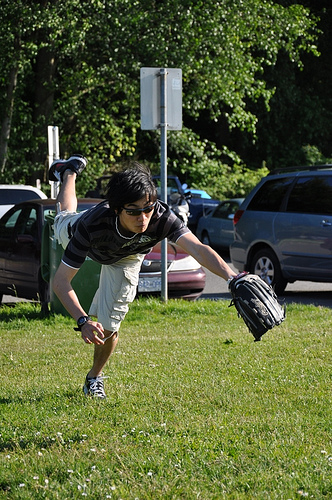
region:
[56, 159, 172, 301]
This man is playing baseball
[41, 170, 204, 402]
Man just caught a ball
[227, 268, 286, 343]
This is a catcher's mitt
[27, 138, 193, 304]
Man is leaning over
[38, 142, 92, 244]
Man's leg is in the air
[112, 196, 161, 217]
Man is wearing sunglasses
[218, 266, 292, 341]
The mitt is black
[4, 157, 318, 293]
A parking lot in the background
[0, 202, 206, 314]
This car is maroon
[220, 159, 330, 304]
This minivan is silver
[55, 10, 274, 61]
The leaves are the color green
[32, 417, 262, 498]
The grass is short and green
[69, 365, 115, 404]
The shoe of the man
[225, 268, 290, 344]
The man is wearing a baseball mitt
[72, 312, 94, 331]
The man has on a watch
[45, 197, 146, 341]
The man is wearing shorts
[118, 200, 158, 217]
The man is wearing sun glasses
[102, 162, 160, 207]
The man has black hair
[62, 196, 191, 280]
The man is wearing a black and grey shirt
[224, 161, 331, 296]
The van is parked in the parking lot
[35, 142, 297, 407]
person bends forward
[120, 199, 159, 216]
sunglasses color black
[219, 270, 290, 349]
the glove of baseball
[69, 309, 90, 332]
a clock on wrist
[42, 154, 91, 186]
blue shoes with white sole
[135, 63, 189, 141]
a sign on the street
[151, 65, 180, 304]
the pole is gray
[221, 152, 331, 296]
car parked on side road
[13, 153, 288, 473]
person on a green field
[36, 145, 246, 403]
person wears tan shorts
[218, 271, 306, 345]
person holding a glove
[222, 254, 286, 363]
the glove is black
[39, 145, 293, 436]
person standing in the grass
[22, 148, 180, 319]
cars parked on the road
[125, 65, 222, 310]
sign posted in the grass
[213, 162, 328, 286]
the car is silver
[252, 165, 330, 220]
black windows on the car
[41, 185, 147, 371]
person wearing tan pants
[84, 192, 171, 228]
person wearing sunglasses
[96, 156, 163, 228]
person has black hair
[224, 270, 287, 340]
A baseball mitt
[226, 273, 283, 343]
A baseball glove in hand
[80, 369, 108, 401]
Shoe on a foot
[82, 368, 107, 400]
Athletic shoe on a foot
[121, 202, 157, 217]
Kid wearing sunglasses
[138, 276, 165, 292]
License plate on a car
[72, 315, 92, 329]
Wrist watch on a hand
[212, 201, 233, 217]
A window on a car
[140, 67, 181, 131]
A sign on a pole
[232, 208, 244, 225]
A rear tail light on a car